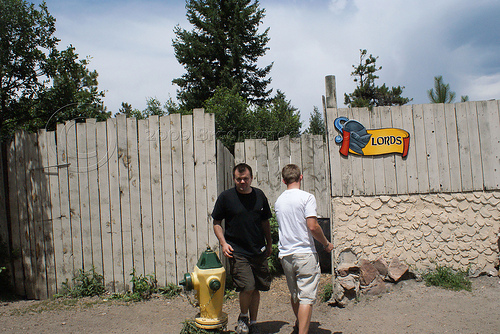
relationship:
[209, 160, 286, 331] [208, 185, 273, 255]
man wearing shirt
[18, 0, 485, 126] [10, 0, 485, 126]
cloud hanging in sky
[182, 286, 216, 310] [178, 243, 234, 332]
chain attached to fire hydrant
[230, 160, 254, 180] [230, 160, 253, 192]
hair growing on head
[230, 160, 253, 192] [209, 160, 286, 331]
head belonging to man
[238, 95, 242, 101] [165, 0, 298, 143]
leaf growing on tree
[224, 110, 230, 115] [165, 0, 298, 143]
leaf growing on tree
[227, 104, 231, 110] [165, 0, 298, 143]
leaf growing on tree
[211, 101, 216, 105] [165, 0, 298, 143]
leaf growing on tree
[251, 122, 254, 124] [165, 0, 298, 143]
leaf growing on tree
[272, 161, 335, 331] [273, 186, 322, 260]
man wearing shirt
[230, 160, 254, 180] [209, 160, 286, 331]
hair belonging to man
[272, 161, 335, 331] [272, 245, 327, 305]
man wearing shorts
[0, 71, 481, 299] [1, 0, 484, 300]
fence standing in background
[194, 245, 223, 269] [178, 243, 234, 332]
top sealing fire hydrant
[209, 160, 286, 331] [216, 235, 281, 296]
man wearing shorts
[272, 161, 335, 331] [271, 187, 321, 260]
man wearing t-shirt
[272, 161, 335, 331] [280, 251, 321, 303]
man wearing pants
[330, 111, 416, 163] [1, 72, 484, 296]
sign hanging on gate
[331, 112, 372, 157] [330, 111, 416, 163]
knight formed on sign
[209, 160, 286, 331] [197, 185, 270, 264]
man wearing shirt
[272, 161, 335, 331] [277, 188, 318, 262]
man wearing shirt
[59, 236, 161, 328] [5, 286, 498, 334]
bush on ground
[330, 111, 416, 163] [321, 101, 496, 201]
sign on wall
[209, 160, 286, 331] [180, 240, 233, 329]
man standing beside fire hydrant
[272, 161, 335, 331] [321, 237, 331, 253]
man wearing watch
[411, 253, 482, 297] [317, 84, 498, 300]
plant in front of wall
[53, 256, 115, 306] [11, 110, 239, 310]
plant in front of wall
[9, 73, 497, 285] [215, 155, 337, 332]
wall behind men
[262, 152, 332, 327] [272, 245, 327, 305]
guy wearing shorts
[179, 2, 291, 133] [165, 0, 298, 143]
leaves on tree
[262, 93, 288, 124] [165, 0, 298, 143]
leaves on tree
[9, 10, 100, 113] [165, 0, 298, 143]
leaves on tree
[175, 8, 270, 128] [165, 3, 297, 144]
leaves on tree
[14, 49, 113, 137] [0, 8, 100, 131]
leaves on tree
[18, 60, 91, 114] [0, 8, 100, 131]
leaves on tree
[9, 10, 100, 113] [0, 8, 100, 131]
leaves on tree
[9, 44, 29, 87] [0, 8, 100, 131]
leaves on tree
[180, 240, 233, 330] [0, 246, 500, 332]
hydrant on ground